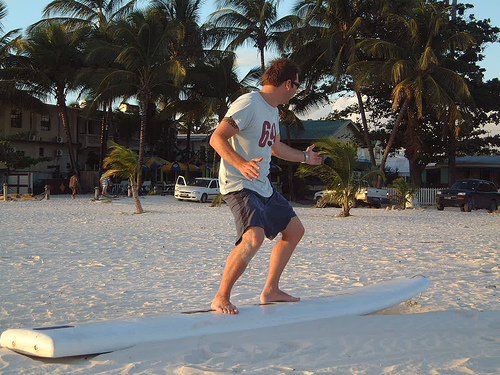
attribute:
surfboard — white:
[13, 277, 415, 359]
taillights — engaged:
[363, 186, 398, 199]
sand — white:
[358, 210, 463, 271]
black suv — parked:
[430, 174, 498, 219]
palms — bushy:
[1, 2, 473, 218]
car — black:
[430, 174, 498, 218]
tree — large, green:
[294, 11, 481, 217]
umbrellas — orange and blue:
[148, 150, 213, 177]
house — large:
[28, 75, 88, 173]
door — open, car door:
[162, 168, 227, 222]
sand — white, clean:
[1, 195, 498, 373]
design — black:
[31, 322, 72, 335]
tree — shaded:
[19, 18, 98, 158]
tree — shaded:
[80, 10, 130, 181]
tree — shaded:
[97, 7, 190, 173]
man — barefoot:
[209, 55, 325, 315]